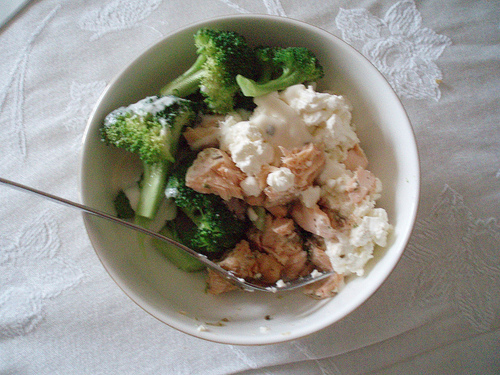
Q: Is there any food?
A: Yes, there is food.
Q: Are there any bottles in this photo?
A: No, there are no bottles.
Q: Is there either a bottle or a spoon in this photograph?
A: No, there are no bottles or spoons.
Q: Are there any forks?
A: Yes, there is a fork.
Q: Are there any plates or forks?
A: Yes, there is a fork.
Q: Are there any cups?
A: No, there are no cups.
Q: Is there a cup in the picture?
A: No, there are no cups.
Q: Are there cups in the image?
A: No, there are no cups.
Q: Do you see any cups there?
A: No, there are no cups.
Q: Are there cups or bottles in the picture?
A: No, there are no cups or bottles.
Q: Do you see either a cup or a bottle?
A: No, there are no cups or bottles.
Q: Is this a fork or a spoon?
A: This is a fork.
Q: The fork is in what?
A: The fork is in the bowl.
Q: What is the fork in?
A: The fork is in the bowl.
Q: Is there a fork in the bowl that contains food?
A: Yes, there is a fork in the bowl.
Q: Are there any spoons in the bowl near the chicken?
A: No, there is a fork in the bowl.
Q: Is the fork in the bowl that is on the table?
A: Yes, the fork is in the bowl.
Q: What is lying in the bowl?
A: The fork is lying in the bowl.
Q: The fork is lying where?
A: The fork is lying in the bowl.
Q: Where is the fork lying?
A: The fork is lying in the bowl.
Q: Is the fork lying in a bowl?
A: Yes, the fork is lying in a bowl.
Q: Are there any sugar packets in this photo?
A: No, there are no sugar packets.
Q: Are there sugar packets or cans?
A: No, there are no sugar packets or cans.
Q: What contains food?
A: The bowl contains food.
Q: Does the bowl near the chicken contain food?
A: Yes, the bowl contains food.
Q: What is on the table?
A: The bowl is on the table.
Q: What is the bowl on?
A: The bowl is on the table.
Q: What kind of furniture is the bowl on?
A: The bowl is on the table.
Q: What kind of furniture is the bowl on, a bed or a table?
A: The bowl is on a table.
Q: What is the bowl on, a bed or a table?
A: The bowl is on a table.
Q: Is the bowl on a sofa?
A: No, the bowl is on the table.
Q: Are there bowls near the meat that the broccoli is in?
A: Yes, there is a bowl near the chicken.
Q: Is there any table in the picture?
A: Yes, there is a table.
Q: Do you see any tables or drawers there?
A: Yes, there is a table.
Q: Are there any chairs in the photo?
A: No, there are no chairs.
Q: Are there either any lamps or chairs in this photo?
A: No, there are no chairs or lamps.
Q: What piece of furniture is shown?
A: The piece of furniture is a table.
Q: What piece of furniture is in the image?
A: The piece of furniture is a table.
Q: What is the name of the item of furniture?
A: The piece of furniture is a table.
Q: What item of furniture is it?
A: The piece of furniture is a table.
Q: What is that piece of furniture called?
A: This is a table.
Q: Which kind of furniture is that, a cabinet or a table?
A: This is a table.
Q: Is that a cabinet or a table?
A: That is a table.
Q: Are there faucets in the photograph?
A: No, there are no faucets.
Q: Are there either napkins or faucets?
A: No, there are no faucets or napkins.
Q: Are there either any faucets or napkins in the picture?
A: No, there are no faucets or napkins.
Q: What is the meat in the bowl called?
A: The meat is chicken.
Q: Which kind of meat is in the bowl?
A: The meat is chicken.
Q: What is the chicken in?
A: The chicken is in the bowl.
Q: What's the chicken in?
A: The chicken is in the bowl.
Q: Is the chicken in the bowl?
A: Yes, the chicken is in the bowl.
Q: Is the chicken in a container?
A: No, the chicken is in the bowl.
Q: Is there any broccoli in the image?
A: Yes, there is broccoli.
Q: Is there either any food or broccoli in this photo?
A: Yes, there is broccoli.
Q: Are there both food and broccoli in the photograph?
A: Yes, there are both broccoli and food.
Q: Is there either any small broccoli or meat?
A: Yes, there is small broccoli.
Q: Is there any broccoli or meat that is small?
A: Yes, the broccoli is small.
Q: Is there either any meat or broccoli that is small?
A: Yes, the broccoli is small.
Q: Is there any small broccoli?
A: Yes, there is small broccoli.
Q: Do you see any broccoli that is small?
A: Yes, there is small broccoli.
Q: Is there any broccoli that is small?
A: Yes, there is broccoli that is small.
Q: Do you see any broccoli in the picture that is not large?
A: Yes, there is small broccoli.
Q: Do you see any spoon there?
A: No, there are no spoons.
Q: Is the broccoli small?
A: Yes, the broccoli is small.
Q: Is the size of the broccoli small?
A: Yes, the broccoli is small.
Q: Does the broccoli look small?
A: Yes, the broccoli is small.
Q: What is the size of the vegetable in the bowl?
A: The broccoli is small.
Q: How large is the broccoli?
A: The broccoli is small.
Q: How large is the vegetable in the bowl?
A: The broccoli is small.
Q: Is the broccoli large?
A: No, the broccoli is small.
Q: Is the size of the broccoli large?
A: No, the broccoli is small.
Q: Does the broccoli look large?
A: No, the broccoli is small.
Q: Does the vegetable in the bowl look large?
A: No, the broccoli is small.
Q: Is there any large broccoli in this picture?
A: No, there is broccoli but it is small.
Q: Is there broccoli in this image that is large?
A: No, there is broccoli but it is small.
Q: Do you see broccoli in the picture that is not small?
A: No, there is broccoli but it is small.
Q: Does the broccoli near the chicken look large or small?
A: The broccoli is small.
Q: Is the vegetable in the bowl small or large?
A: The broccoli is small.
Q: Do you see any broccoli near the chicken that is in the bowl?
A: Yes, there is broccoli near the chicken.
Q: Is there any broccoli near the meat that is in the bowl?
A: Yes, there is broccoli near the chicken.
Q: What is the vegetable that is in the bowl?
A: The vegetable is broccoli.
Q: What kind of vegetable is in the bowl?
A: The vegetable is broccoli.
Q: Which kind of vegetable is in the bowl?
A: The vegetable is broccoli.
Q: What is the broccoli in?
A: The broccoli is in the bowl.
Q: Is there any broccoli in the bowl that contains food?
A: Yes, there is broccoli in the bowl.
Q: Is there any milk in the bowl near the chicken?
A: No, there is broccoli in the bowl.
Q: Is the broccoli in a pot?
A: No, the broccoli is in a bowl.